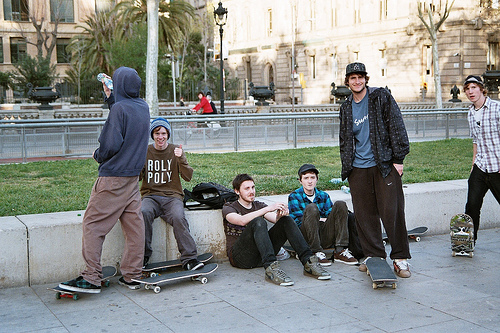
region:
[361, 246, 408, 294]
A SKATEBOARD ON THE SIDEWALK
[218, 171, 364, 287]
TWO GUYS SITTING ON THE GROUND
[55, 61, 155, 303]
GUY DRINKING BOTTLED WATER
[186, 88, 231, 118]
PERSON IN THE DISTANCE WEARING A RED SHIRT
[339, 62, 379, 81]
A BLACK HAT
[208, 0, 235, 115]
A STREET LAMP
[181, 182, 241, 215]
A BLACK BACKPACK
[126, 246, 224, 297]
TWO SKATEBOARDS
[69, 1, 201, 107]
TREES IN THE BACKGROUND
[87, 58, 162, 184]
BLUE HOODED SWEAT SHIRT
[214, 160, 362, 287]
two boys are sitting down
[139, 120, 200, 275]
a boy is wearing a brown shirt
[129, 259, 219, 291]
one skateboard has no one on it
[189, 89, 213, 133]
a person wearing red in background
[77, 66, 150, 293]
a boy is drinking water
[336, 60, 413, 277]
one boy is smiling at the camera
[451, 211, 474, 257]
one skateboard is popped up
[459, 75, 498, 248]
one boy is wearing a plaid shirt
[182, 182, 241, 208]
a backpack on the ground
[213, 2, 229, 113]
a street lamp in the background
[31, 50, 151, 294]
Boy is drinking water.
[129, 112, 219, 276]
Boy is sitting on concrete wall.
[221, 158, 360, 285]
Two boys leaning against wall.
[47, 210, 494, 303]
Seven skateboards on sidewalk.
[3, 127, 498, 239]
Grass is green and short.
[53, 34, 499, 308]
Six boys lounging around.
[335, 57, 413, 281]
Boy in hat is smiling.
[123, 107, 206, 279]
Boy on wall is smiling.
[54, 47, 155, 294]
Boy has back to camera.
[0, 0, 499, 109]
Tall building in background.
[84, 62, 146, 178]
A person in a blue hoodie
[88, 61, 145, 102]
A person drinking water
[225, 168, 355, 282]
Two people sitting on the ground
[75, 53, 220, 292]
Two people and three skateboards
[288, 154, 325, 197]
A man in a black cap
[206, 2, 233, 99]
An art deco street lamp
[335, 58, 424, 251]
A man in black pants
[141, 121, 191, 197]
A man in a brown shirt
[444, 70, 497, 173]
A man in a plaid shirt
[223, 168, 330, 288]
A man wearing sneakers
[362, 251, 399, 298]
a skateboard on the ground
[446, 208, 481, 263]
a skateboard being lifted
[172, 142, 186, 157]
a thumbs up from kid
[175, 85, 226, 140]
two bike riders in the background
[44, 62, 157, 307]
a kid drinking from a bottle of water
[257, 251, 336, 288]
a pair of gray and white tennis shoes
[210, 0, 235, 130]
a lamp post in the background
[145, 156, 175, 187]
the words ROLY POLY written in white lettering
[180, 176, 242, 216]
a black backpack on the concrete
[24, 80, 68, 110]
a cast-iron scultpure